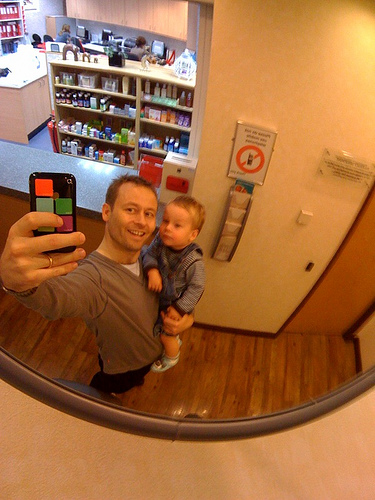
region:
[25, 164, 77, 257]
color blocks on the back of the phone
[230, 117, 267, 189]
cell phone prohibited sign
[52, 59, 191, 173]
bottles of prescription medication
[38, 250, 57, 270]
man is wearing a wedding ring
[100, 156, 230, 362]
man is holding a little boy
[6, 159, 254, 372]
man is taking a selfie with the boy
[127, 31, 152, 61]
person sitting at a desk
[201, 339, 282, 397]
wood floor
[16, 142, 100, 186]
grey counter top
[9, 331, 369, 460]
reflection in the mirror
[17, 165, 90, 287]
a man holding a cell phone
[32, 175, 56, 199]
an orange square on a mobile phone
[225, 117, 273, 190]
a no cell phone sign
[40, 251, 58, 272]
a man wearing a wedding ring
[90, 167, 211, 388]
a man holding a baby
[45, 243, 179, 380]
a man wearing a brown shirt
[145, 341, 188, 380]
a baby wearing a white shoe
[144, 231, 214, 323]
a baby wearing a blue and white shirt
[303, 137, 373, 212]
a sign on a wall near a door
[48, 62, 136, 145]
different types medicine on a shelf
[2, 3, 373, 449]
the security mirror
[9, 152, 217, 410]
the man at the pharmacy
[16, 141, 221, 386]
the man holding the baby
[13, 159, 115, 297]
the man holding the cellphone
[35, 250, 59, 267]
the ring on the finger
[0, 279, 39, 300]
the watch on the wrist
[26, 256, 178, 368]
the man wearing brown sweater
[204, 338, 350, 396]
the floor is wooden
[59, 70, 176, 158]
medication on the shelves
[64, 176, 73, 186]
the camera of the phone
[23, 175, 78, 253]
Man holding a camera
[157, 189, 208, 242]
baby with blond hair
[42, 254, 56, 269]
man wearing a wedding ring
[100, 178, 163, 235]
man with blond hair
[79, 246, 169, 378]
man with brown hair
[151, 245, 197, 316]
baby wearing a blue shirt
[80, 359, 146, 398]
man wearing black pants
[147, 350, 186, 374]
baby wearing blue shoes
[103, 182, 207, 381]
man holding a baby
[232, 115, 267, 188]
sign on the wall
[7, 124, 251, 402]
Man taking a picture of his child with a smart phone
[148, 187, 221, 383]
Little boy wearing blue overalls with a gray shirt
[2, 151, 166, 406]
A smiling father with brown hair and a brown shirt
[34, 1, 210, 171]
A variety of medication on shelves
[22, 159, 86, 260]
A smartphone with red, gray, green and purple squares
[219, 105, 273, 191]
A no smoking sign on the wall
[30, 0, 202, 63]
Two women working on computers behind the counter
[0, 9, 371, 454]
Reflection of mirror showing the front of a pharmacy counter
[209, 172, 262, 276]
Five tier brochure holders on door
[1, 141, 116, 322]
Wedding band on father's left hand